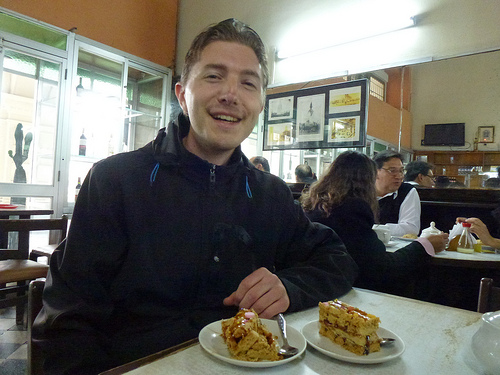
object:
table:
[102, 200, 500, 375]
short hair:
[180, 16, 270, 91]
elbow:
[321, 244, 361, 296]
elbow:
[367, 252, 401, 286]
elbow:
[394, 220, 421, 237]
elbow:
[29, 309, 73, 355]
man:
[367, 149, 420, 237]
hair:
[371, 150, 405, 170]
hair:
[180, 17, 269, 94]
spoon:
[274, 312, 300, 356]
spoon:
[376, 336, 394, 348]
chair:
[0, 213, 68, 330]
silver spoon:
[378, 337, 395, 346]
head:
[174, 17, 266, 151]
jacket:
[29, 111, 358, 375]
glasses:
[382, 168, 405, 174]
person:
[27, 19, 355, 375]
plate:
[197, 308, 306, 368]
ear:
[175, 81, 189, 116]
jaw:
[209, 133, 242, 151]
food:
[219, 307, 284, 361]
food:
[318, 299, 381, 356]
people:
[298, 149, 449, 278]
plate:
[301, 298, 405, 365]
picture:
[262, 78, 366, 151]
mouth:
[207, 110, 241, 128]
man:
[28, 16, 354, 374]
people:
[29, 17, 358, 375]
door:
[64, 51, 127, 238]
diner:
[198, 299, 406, 369]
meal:
[218, 298, 381, 363]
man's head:
[371, 150, 405, 192]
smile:
[199, 88, 254, 137]